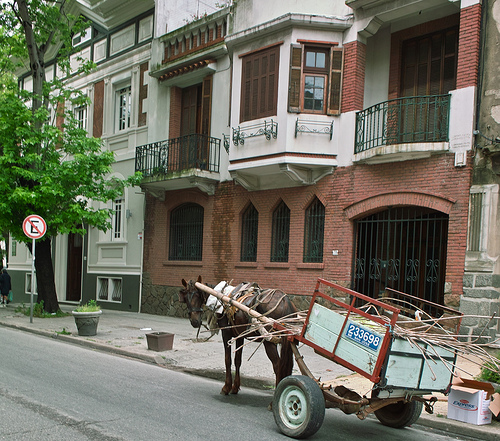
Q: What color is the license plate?
A: Blue.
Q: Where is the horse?
A: In the street.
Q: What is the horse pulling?
A: A cart.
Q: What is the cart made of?
A: Wood and metal.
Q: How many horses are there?
A: One.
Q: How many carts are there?
A: One.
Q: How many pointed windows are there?
A: Three.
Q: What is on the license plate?
A: 233698.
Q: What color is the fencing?
A: Green.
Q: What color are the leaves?
A: Green.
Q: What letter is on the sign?
A: E.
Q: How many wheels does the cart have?
A: Two.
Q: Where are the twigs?
A: The cart.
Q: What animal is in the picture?
A: A horse.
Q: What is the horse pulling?
A: A wagon.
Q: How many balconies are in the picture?
A: Two.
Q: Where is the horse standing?
A: Next to curb.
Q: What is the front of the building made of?
A: Brick.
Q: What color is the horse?
A: Brown.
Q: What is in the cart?
A: Sticks.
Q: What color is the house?
A: Red.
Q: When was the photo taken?
A: Daytime.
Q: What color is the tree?
A: Green.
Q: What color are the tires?
A: Black.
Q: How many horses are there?
A: One.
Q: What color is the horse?
A: Brown.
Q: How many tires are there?
A: Two.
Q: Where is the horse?
A: In front of the cart.